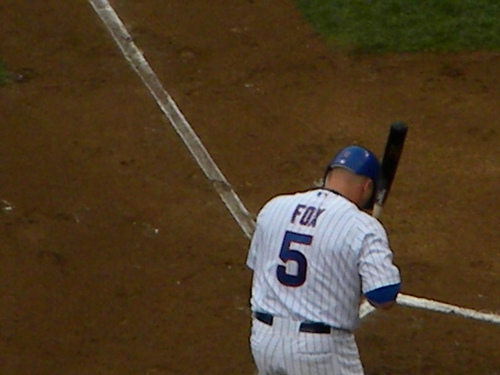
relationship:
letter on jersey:
[291, 194, 308, 224] [246, 180, 406, 324]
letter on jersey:
[297, 204, 314, 225] [238, 183, 407, 333]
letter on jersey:
[303, 202, 327, 228] [246, 180, 406, 324]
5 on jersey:
[273, 230, 313, 286] [238, 183, 407, 333]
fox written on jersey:
[287, 203, 324, 228] [245, 186, 402, 330]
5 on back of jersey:
[273, 231, 317, 290] [246, 180, 406, 324]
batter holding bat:
[244, 147, 402, 374] [367, 121, 413, 221]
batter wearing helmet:
[244, 147, 402, 374] [329, 145, 386, 178]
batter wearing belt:
[244, 147, 402, 374] [253, 309, 334, 336]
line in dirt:
[89, 0, 256, 235] [2, 0, 497, 370]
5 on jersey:
[273, 230, 313, 286] [245, 186, 402, 330]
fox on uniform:
[286, 199, 319, 235] [244, 188, 399, 374]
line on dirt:
[89, 0, 256, 235] [2, 0, 497, 370]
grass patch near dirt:
[295, 3, 499, 58] [2, 0, 497, 370]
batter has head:
[244, 147, 402, 374] [321, 139, 379, 211]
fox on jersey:
[287, 203, 324, 228] [238, 183, 407, 333]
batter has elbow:
[244, 144, 404, 374] [364, 277, 404, 315]